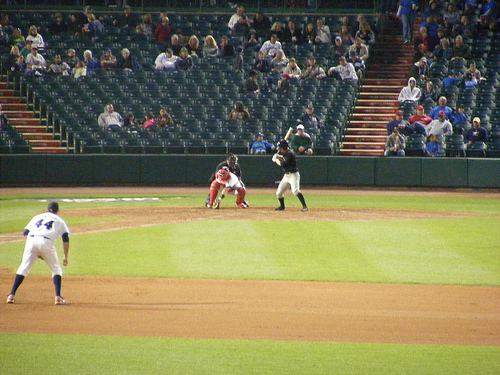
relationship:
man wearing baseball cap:
[272, 138, 310, 213] [213, 168, 228, 182]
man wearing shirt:
[272, 138, 310, 213] [280, 149, 297, 170]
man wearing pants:
[272, 138, 310, 213] [277, 170, 301, 197]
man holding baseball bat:
[272, 138, 310, 213] [275, 127, 293, 153]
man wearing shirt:
[6, 200, 72, 302] [26, 211, 68, 239]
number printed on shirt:
[33, 217, 55, 229] [26, 211, 68, 239]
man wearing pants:
[6, 200, 72, 302] [16, 236, 63, 278]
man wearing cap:
[6, 200, 72, 302] [48, 200, 59, 211]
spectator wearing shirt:
[432, 96, 452, 119] [431, 105, 451, 120]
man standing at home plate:
[272, 138, 310, 213] [251, 207, 273, 212]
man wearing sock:
[272, 138, 310, 213] [279, 197, 286, 208]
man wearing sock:
[272, 138, 310, 213] [298, 192, 308, 208]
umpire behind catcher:
[212, 154, 243, 180] [209, 167, 249, 209]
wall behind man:
[0, 155, 500, 187] [272, 138, 310, 213]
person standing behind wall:
[290, 124, 314, 154] [0, 155, 500, 187]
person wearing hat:
[290, 124, 314, 154] [297, 124, 305, 130]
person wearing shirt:
[290, 124, 314, 154] [291, 133, 312, 151]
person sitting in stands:
[117, 48, 140, 70] [0, 3, 499, 156]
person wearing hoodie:
[397, 75, 421, 102] [397, 75, 421, 101]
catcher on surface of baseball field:
[209, 167, 249, 209] [0, 187, 500, 374]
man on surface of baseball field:
[272, 138, 310, 213] [0, 187, 500, 374]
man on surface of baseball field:
[6, 200, 72, 302] [0, 187, 500, 374]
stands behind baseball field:
[0, 3, 499, 156] [0, 187, 500, 374]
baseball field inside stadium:
[0, 187, 500, 374] [0, 0, 500, 374]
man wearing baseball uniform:
[272, 138, 310, 213] [276, 151, 308, 212]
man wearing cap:
[272, 138, 310, 213] [48, 200, 59, 211]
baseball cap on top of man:
[213, 168, 228, 182] [272, 138, 310, 213]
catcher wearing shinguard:
[209, 167, 249, 209] [237, 186, 246, 204]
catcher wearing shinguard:
[209, 167, 249, 209] [210, 182, 220, 204]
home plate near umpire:
[251, 207, 273, 212] [212, 154, 243, 180]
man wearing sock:
[6, 200, 72, 302] [53, 275, 64, 295]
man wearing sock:
[6, 200, 72, 302] [11, 273, 24, 294]